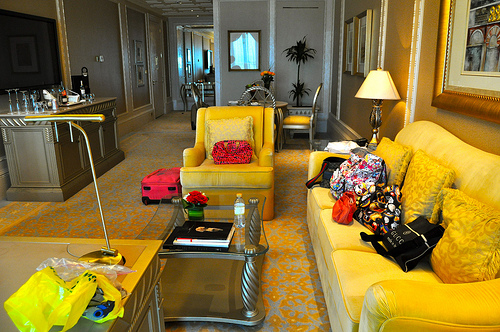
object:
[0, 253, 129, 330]
bag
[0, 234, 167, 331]
counter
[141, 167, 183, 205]
bag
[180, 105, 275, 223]
chair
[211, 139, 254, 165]
bag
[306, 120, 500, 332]
couch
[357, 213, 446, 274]
purses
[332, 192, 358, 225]
purses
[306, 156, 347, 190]
purses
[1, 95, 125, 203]
bar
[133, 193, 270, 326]
coffee table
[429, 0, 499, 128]
picture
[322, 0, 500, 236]
wall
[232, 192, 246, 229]
bottle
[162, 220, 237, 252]
books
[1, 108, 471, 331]
floor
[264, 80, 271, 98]
vase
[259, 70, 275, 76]
flowers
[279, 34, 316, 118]
plant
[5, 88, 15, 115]
glasses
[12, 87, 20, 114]
glasses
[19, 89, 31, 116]
glasses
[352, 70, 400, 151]
lamp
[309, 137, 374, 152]
table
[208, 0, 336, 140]
wall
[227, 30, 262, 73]
mirror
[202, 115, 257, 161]
pillow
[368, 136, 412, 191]
pillow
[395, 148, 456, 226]
pillow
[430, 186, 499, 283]
pillow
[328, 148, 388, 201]
bag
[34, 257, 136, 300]
plastic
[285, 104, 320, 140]
pot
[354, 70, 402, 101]
shade